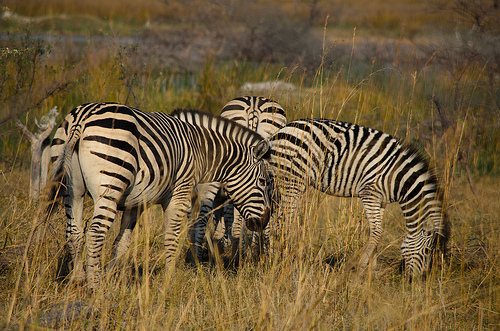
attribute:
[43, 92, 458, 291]
zebras — many, grouped, existing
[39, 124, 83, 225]
tail — existing, fluffy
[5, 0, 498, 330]
grass — long, parched, yellow, tall, existing, green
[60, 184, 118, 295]
legs — long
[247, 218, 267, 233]
mouth — existing, black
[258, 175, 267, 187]
eye — existing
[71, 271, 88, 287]
hoof — existing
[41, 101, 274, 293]
zebra — standing, grazing, striped, eating grass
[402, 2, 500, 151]
tree — dead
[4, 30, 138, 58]
river — in distance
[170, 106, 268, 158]
mane — black, white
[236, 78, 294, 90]
tree — grey, fallen, dead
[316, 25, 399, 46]
dirt — brown